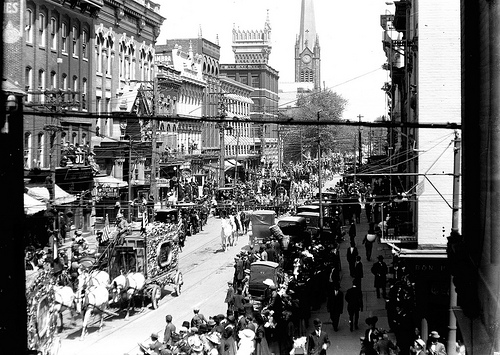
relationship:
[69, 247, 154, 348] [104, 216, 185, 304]
horse pulling carriage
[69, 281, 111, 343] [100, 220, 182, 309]
horse pulling carriage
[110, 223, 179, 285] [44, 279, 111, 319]
carriage pulled by horses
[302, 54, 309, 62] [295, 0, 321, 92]
clock on tower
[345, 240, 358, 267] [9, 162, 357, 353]
person walking on street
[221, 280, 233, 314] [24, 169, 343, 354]
person walking on road